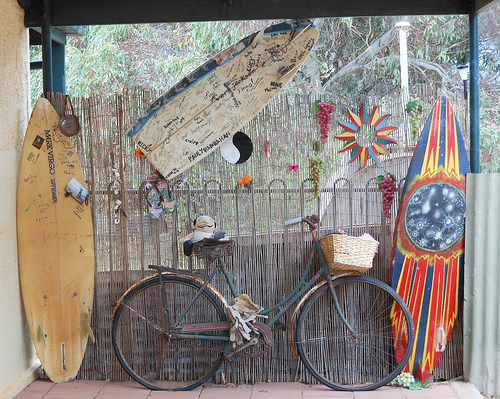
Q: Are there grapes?
A: Yes, there are grapes.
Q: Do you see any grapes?
A: Yes, there are grapes.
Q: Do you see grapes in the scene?
A: Yes, there are grapes.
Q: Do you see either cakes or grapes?
A: Yes, there are grapes.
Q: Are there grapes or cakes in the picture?
A: Yes, there are grapes.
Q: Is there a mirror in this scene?
A: No, there are no mirrors.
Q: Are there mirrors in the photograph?
A: No, there are no mirrors.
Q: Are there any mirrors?
A: No, there are no mirrors.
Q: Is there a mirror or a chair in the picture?
A: No, there are no mirrors or chairs.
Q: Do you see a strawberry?
A: No, there are no strawberries.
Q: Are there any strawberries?
A: No, there are no strawberries.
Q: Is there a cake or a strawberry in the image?
A: No, there are no strawberries or cakes.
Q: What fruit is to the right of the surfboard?
A: The fruit is a grape.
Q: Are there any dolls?
A: Yes, there is a doll.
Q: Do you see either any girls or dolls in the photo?
A: Yes, there is a doll.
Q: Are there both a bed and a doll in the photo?
A: No, there is a doll but no beds.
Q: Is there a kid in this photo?
A: No, there are no children.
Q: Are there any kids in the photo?
A: No, there are no kids.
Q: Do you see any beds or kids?
A: No, there are no kids or beds.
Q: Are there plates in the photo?
A: No, there are no plates.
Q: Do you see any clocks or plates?
A: No, there are no plates or clocks.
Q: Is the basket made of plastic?
A: No, the basket is made of wicker.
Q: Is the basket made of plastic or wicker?
A: The basket is made of wicker.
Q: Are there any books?
A: No, there are no books.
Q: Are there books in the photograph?
A: No, there are no books.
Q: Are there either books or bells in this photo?
A: No, there are no books or bells.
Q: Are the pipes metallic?
A: Yes, the pipes are metallic.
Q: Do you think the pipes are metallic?
A: Yes, the pipes are metallic.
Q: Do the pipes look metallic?
A: Yes, the pipes are metallic.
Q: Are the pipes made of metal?
A: Yes, the pipes are made of metal.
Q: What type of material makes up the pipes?
A: The pipes are made of metal.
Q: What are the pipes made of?
A: The pipes are made of metal.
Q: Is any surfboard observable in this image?
A: Yes, there is a surfboard.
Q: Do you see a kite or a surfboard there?
A: Yes, there is a surfboard.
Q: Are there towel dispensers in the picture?
A: No, there are no towel dispensers.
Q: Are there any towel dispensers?
A: No, there are no towel dispensers.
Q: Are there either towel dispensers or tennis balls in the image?
A: No, there are no towel dispensers or tennis balls.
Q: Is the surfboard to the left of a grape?
A: Yes, the surfboard is to the left of a grape.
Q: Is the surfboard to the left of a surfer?
A: No, the surfboard is to the left of a grape.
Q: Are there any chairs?
A: No, there are no chairs.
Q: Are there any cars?
A: No, there are no cars.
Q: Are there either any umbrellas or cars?
A: No, there are no cars or umbrellas.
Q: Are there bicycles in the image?
A: Yes, there is a bicycle.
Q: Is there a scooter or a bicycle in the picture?
A: Yes, there is a bicycle.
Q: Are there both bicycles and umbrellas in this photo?
A: No, there is a bicycle but no umbrellas.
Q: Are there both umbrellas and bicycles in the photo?
A: No, there is a bicycle but no umbrellas.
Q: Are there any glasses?
A: No, there are no glasses.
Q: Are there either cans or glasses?
A: No, there are no glasses or cans.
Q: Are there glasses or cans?
A: No, there are no glasses or cans.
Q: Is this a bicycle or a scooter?
A: This is a bicycle.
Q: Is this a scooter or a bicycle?
A: This is a bicycle.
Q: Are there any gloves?
A: Yes, there are gloves.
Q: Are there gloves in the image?
A: Yes, there are gloves.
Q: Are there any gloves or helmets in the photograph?
A: Yes, there are gloves.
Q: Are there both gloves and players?
A: No, there are gloves but no players.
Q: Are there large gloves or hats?
A: Yes, there are large gloves.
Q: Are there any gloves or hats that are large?
A: Yes, the gloves are large.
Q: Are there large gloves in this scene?
A: Yes, there are large gloves.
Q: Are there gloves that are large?
A: Yes, there are gloves that are large.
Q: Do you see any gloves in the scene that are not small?
A: Yes, there are large gloves.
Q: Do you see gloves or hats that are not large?
A: No, there are gloves but they are large.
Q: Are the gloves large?
A: Yes, the gloves are large.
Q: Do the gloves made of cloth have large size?
A: Yes, the gloves are large.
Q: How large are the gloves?
A: The gloves are large.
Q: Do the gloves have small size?
A: No, the gloves are large.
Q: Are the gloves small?
A: No, the gloves are large.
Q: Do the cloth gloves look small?
A: No, the gloves are large.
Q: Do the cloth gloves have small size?
A: No, the gloves are large.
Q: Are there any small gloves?
A: No, there are gloves but they are large.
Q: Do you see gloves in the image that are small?
A: No, there are gloves but they are large.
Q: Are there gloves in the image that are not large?
A: No, there are gloves but they are large.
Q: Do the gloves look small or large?
A: The gloves are large.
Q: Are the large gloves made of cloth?
A: Yes, the gloves are made of cloth.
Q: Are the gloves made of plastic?
A: No, the gloves are made of cloth.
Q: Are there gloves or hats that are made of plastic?
A: No, there are gloves but they are made of cloth.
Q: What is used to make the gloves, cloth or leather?
A: The gloves are made of cloth.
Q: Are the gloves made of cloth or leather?
A: The gloves are made of cloth.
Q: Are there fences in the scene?
A: Yes, there is a fence.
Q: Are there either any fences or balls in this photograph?
A: Yes, there is a fence.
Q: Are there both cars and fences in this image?
A: No, there is a fence but no cars.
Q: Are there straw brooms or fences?
A: Yes, there is a straw fence.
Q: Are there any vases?
A: No, there are no vases.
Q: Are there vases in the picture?
A: No, there are no vases.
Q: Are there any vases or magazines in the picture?
A: No, there are no vases or magazines.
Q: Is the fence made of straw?
A: Yes, the fence is made of straw.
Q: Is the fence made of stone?
A: No, the fence is made of straw.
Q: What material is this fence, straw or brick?
A: The fence is made of straw.